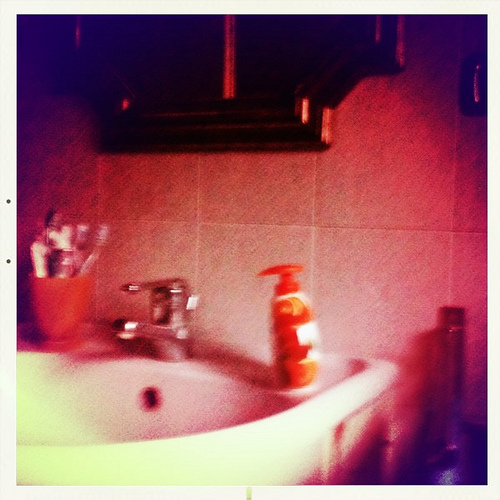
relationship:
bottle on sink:
[247, 254, 321, 389] [27, 292, 402, 485]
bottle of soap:
[247, 254, 321, 389] [248, 267, 331, 390]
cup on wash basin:
[29, 272, 95, 343] [19, 320, 398, 490]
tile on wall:
[306, 224, 470, 361] [23, 83, 479, 362]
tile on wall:
[311, 224, 451, 361] [17, 16, 483, 419]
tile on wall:
[195, 222, 317, 354] [17, 16, 483, 419]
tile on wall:
[95, 220, 200, 332] [20, 20, 483, 341]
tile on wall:
[198, 153, 318, 223] [37, 107, 479, 453]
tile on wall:
[198, 153, 318, 223] [16, 155, 483, 205]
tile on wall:
[95, 153, 199, 221] [184, 211, 479, 255]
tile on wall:
[95, 162, 200, 227] [337, 123, 439, 259]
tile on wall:
[210, 153, 319, 223] [107, 148, 434, 258]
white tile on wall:
[316, 76, 456, 234] [45, 151, 499, 355]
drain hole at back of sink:
[141, 385, 162, 413] [15, 300, 389, 470]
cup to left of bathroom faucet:
[29, 272, 95, 343] [111, 277, 200, 361]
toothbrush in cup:
[74, 223, 109, 278] [29, 272, 95, 343]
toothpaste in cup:
[27, 242, 54, 296] [29, 272, 95, 343]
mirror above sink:
[76, 23, 341, 158] [12, 311, 397, 474]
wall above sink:
[20, 20, 483, 341] [15, 336, 295, 456]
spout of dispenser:
[240, 261, 297, 284] [256, 261, 323, 389]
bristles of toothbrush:
[97, 225, 109, 244] [74, 223, 109, 278]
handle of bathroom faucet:
[119, 277, 188, 297] [111, 277, 200, 361]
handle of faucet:
[122, 278, 189, 290] [114, 315, 174, 346]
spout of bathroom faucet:
[103, 305, 193, 356] [108, 250, 203, 373]